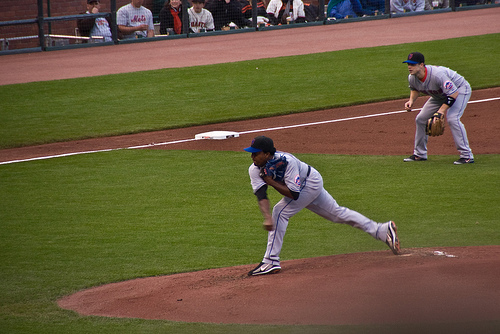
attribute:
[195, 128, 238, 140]
base — white, square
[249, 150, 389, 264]
uniform — white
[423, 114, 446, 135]
glove — brown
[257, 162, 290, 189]
glove — blue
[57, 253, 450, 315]
mount — dirt pitchers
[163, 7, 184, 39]
scarf — orange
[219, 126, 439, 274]
baseball pitcher — throwing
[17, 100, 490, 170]
foul line — white marked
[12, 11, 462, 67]
stadium — baseball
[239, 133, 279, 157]
baseball cap — blue and black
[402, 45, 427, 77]
baseball cap — blue and black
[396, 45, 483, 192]
baseball player — watching a play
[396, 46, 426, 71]
hat — baseball player's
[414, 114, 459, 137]
glove — baseball player's, brown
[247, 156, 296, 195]
glove — blue, baseball player's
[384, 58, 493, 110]
shirt — red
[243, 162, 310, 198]
uniform — white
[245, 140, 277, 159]
cap — black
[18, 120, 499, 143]
line — white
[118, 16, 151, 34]
t-shirt — Mets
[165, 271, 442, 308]
dirt — bare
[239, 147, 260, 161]
brim — blue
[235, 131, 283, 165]
baseball cap — black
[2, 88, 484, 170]
path — bare, dirt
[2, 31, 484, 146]
grass — green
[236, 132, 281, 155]
cap — black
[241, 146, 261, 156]
rim — blue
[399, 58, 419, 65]
rim — blue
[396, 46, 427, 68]
cap — black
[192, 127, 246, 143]
base — white, square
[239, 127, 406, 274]
pitcher — black belt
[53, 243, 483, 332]
mound — brown, dirt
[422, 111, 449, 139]
glove — brown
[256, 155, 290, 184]
glove — blue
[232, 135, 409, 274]
player —  hunched over